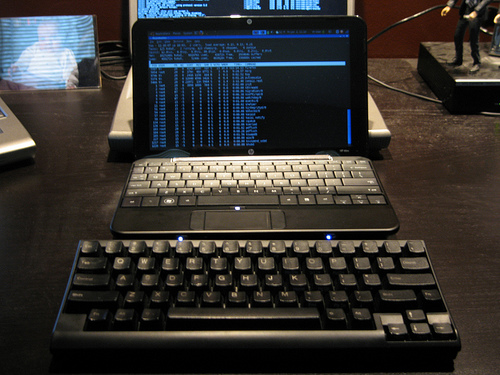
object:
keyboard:
[50, 239, 463, 362]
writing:
[148, 30, 271, 150]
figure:
[440, 0, 489, 73]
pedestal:
[416, 41, 497, 116]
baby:
[7, 19, 78, 91]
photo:
[0, 14, 102, 94]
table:
[1, 56, 498, 374]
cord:
[367, 2, 499, 117]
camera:
[247, 19, 253, 25]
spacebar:
[165, 308, 321, 331]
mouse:
[189, 208, 287, 231]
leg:
[468, 12, 480, 73]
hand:
[440, 6, 451, 17]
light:
[326, 234, 332, 239]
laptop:
[107, 15, 402, 238]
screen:
[134, 0, 349, 20]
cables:
[96, 40, 132, 81]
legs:
[447, 10, 469, 67]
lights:
[177, 236, 183, 242]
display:
[131, 15, 368, 153]